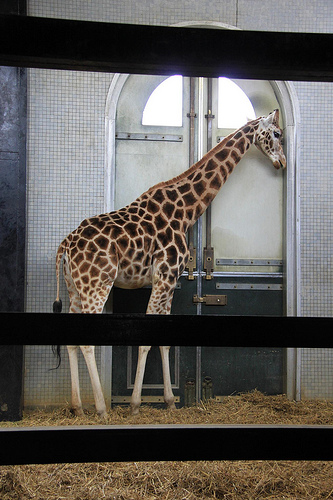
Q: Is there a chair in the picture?
A: No, there are no chairs.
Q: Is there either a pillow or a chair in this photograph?
A: No, there are no chairs or pillows.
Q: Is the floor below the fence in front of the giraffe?
A: Yes, the floor is below the fence.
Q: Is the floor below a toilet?
A: No, the floor is below the fence.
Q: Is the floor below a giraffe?
A: Yes, the floor is below a giraffe.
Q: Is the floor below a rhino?
A: No, the floor is below a giraffe.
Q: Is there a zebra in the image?
A: No, there are no zebras.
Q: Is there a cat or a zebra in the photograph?
A: No, there are no zebras or cats.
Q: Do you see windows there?
A: Yes, there is a window.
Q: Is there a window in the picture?
A: Yes, there is a window.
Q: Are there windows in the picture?
A: Yes, there is a window.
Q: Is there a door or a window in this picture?
A: Yes, there is a window.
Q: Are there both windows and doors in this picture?
A: Yes, there are both a window and a door.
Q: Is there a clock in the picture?
A: No, there are no clocks.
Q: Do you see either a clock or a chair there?
A: No, there are no clocks or chairs.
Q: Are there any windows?
A: Yes, there is a window.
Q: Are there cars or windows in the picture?
A: Yes, there is a window.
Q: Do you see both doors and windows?
A: Yes, there are both a window and a door.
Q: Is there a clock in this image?
A: No, there are no clocks.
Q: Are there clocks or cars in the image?
A: No, there are no clocks or cars.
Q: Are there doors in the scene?
A: Yes, there is a door.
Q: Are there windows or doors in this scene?
A: Yes, there is a door.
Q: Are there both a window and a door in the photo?
A: Yes, there are both a door and a window.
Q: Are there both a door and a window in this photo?
A: Yes, there are both a door and a window.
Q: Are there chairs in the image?
A: No, there are no chairs.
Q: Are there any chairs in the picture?
A: No, there are no chairs.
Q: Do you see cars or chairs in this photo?
A: No, there are no chairs or cars.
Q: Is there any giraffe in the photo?
A: Yes, there is a giraffe.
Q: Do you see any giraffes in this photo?
A: Yes, there is a giraffe.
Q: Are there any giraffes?
A: Yes, there is a giraffe.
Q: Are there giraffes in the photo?
A: Yes, there is a giraffe.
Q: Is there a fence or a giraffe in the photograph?
A: Yes, there is a giraffe.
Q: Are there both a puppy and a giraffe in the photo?
A: No, there is a giraffe but no puppies.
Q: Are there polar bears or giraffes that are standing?
A: Yes, the giraffe is standing.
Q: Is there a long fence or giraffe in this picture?
A: Yes, there is a long giraffe.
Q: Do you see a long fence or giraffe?
A: Yes, there is a long giraffe.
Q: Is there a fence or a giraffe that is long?
A: Yes, the giraffe is long.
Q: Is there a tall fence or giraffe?
A: Yes, there is a tall giraffe.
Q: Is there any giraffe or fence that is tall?
A: Yes, the giraffe is tall.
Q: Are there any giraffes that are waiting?
A: Yes, there is a giraffe that is waiting.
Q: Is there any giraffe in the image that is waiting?
A: Yes, there is a giraffe that is waiting.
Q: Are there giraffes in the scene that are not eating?
A: Yes, there is a giraffe that is waiting.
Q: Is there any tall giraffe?
A: Yes, there is a tall giraffe.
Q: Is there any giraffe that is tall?
A: Yes, there is a giraffe that is tall.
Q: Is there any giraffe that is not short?
A: Yes, there is a tall giraffe.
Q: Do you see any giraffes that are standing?
A: Yes, there is a giraffe that is standing.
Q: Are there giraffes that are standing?
A: Yes, there is a giraffe that is standing.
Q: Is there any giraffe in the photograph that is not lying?
A: Yes, there is a giraffe that is standing.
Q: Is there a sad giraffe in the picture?
A: Yes, there is a sad giraffe.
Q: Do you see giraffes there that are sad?
A: Yes, there is a giraffe that is sad.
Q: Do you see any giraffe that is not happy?
A: Yes, there is a sad giraffe.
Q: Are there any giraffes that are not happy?
A: Yes, there is a sad giraffe.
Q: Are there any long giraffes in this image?
A: Yes, there is a long giraffe.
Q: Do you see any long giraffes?
A: Yes, there is a long giraffe.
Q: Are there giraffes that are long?
A: Yes, there is a giraffe that is long.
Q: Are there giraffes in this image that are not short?
A: Yes, there is a long giraffe.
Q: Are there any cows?
A: No, there are no cows.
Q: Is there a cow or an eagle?
A: No, there are no cows or eagles.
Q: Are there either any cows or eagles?
A: No, there are no cows or eagles.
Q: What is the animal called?
A: The animal is a giraffe.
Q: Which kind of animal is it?
A: The animal is a giraffe.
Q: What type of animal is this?
A: This is a giraffe.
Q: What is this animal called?
A: This is a giraffe.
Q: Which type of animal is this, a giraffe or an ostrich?
A: This is a giraffe.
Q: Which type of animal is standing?
A: The animal is a giraffe.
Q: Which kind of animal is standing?
A: The animal is a giraffe.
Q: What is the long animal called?
A: The animal is a giraffe.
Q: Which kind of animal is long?
A: The animal is a giraffe.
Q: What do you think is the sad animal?
A: The animal is a giraffe.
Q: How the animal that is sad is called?
A: The animal is a giraffe.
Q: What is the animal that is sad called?
A: The animal is a giraffe.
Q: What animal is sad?
A: The animal is a giraffe.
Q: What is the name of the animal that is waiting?
A: The animal is a giraffe.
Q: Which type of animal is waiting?
A: The animal is a giraffe.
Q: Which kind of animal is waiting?
A: The animal is a giraffe.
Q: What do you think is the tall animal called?
A: The animal is a giraffe.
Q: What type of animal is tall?
A: The animal is a giraffe.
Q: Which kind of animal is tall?
A: The animal is a giraffe.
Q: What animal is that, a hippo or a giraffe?
A: That is a giraffe.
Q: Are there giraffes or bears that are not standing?
A: No, there is a giraffe but it is standing.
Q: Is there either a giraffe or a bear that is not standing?
A: No, there is a giraffe but it is standing.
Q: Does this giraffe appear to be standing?
A: Yes, the giraffe is standing.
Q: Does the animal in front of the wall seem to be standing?
A: Yes, the giraffe is standing.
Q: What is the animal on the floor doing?
A: The giraffe is standing.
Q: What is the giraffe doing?
A: The giraffe is standing.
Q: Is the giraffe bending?
A: No, the giraffe is standing.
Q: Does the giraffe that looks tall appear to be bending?
A: No, the giraffe is standing.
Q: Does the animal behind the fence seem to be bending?
A: No, the giraffe is standing.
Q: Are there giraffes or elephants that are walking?
A: No, there is a giraffe but it is standing.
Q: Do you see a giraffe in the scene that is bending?
A: No, there is a giraffe but it is standing.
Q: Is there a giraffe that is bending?
A: No, there is a giraffe but it is standing.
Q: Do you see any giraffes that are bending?
A: No, there is a giraffe but it is standing.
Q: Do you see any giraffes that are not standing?
A: No, there is a giraffe but it is standing.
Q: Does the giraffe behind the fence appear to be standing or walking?
A: The giraffe is standing.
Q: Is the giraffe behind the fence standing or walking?
A: The giraffe is standing.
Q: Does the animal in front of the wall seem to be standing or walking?
A: The giraffe is standing.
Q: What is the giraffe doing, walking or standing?
A: The giraffe is standing.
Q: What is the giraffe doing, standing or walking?
A: The giraffe is standing.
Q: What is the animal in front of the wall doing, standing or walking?
A: The giraffe is standing.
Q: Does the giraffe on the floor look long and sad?
A: Yes, the giraffe is long and sad.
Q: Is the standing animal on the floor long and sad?
A: Yes, the giraffe is long and sad.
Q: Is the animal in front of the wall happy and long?
A: No, the giraffe is long but sad.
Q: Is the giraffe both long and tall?
A: Yes, the giraffe is long and tall.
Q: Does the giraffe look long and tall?
A: Yes, the giraffe is long and tall.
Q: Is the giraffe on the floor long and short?
A: No, the giraffe is long but tall.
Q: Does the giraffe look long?
A: Yes, the giraffe is long.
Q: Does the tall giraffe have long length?
A: Yes, the giraffe is long.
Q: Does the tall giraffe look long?
A: Yes, the giraffe is long.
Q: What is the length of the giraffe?
A: The giraffe is long.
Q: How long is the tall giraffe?
A: The giraffe is long.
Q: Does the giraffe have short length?
A: No, the giraffe is long.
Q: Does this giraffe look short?
A: No, the giraffe is long.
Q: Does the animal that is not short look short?
A: No, the giraffe is long.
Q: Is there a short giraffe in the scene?
A: No, there is a giraffe but it is long.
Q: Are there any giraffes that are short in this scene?
A: No, there is a giraffe but it is long.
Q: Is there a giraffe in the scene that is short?
A: No, there is a giraffe but it is long.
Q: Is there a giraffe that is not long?
A: No, there is a giraffe but it is long.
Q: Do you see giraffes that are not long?
A: No, there is a giraffe but it is long.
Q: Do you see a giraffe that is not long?
A: No, there is a giraffe but it is long.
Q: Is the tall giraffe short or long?
A: The giraffe is long.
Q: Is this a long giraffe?
A: Yes, this is a long giraffe.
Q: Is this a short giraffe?
A: No, this is a long giraffe.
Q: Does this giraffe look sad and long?
A: Yes, the giraffe is sad and long.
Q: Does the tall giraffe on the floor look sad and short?
A: No, the giraffe is sad but long.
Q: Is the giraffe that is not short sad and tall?
A: Yes, the giraffe is sad and tall.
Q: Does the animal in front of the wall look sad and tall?
A: Yes, the giraffe is sad and tall.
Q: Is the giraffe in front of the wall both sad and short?
A: No, the giraffe is sad but tall.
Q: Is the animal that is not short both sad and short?
A: No, the giraffe is sad but tall.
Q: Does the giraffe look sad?
A: Yes, the giraffe is sad.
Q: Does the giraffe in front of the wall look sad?
A: Yes, the giraffe is sad.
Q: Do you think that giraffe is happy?
A: No, the giraffe is sad.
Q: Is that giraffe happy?
A: No, the giraffe is sad.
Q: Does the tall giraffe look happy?
A: No, the giraffe is sad.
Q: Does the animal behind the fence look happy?
A: No, the giraffe is sad.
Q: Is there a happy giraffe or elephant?
A: No, there is a giraffe but it is sad.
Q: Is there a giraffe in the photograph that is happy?
A: No, there is a giraffe but it is sad.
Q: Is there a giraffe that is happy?
A: No, there is a giraffe but it is sad.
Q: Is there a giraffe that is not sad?
A: No, there is a giraffe but it is sad.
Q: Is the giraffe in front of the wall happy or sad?
A: The giraffe is sad.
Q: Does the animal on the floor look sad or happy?
A: The giraffe is sad.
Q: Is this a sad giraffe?
A: Yes, this is a sad giraffe.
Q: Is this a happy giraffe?
A: No, this is a sad giraffe.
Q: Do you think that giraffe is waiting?
A: Yes, the giraffe is waiting.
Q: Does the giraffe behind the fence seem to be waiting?
A: Yes, the giraffe is waiting.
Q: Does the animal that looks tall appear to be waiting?
A: Yes, the giraffe is waiting.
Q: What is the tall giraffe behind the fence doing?
A: The giraffe is waiting.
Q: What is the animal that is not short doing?
A: The giraffe is waiting.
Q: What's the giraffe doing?
A: The giraffe is waiting.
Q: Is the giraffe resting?
A: No, the giraffe is waiting.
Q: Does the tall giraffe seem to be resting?
A: No, the giraffe is waiting.